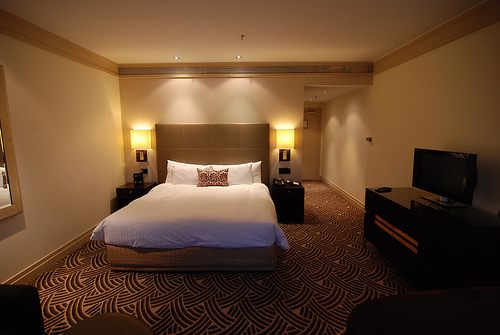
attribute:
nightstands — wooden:
[106, 169, 315, 224]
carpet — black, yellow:
[39, 269, 173, 332]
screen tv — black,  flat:
[410, 145, 491, 201]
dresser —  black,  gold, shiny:
[350, 180, 488, 289]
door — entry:
[301, 102, 322, 180]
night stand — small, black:
[266, 176, 311, 226]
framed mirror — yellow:
[1, 65, 31, 232]